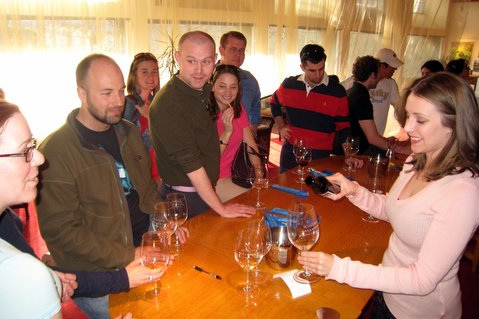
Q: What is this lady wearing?
A: Pink top.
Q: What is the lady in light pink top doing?
A: Pouring wine in the glass.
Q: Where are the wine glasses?
A: On the table.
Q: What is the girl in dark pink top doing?
A: Smiling.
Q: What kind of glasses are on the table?
A: Wine.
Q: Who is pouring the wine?
A: The woman in pink.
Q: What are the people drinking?
A: Wine.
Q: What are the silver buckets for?
A: Spitting into.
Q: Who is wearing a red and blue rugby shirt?
A: The brown haired man in the middle of the group.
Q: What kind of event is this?
A: Wine tasting.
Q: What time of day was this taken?
A: Evening.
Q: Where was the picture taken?
A: In a room.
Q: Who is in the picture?
A: A group of people.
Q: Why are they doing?
A: Drinking wine.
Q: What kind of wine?
A: White wine.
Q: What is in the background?
A: Windows.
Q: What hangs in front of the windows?
A: Curtains.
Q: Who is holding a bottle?
A: A young woman.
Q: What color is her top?
A: Pink.